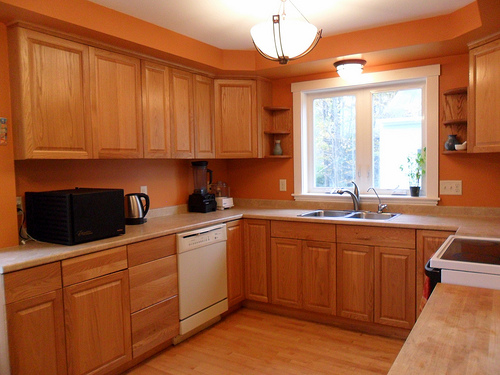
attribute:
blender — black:
[187, 156, 219, 218]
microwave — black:
[21, 180, 134, 250]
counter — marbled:
[1, 172, 258, 374]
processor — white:
[209, 178, 239, 212]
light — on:
[332, 56, 370, 82]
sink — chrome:
[287, 179, 400, 226]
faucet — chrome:
[337, 177, 366, 217]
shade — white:
[246, 10, 327, 70]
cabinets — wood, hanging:
[7, 19, 264, 167]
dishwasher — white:
[168, 225, 241, 334]